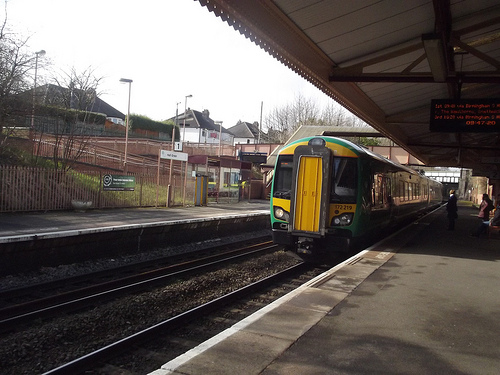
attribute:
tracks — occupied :
[42, 258, 327, 371]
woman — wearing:
[260, 128, 409, 253]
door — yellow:
[293, 155, 320, 230]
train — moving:
[265, 139, 452, 256]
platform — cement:
[147, 199, 498, 374]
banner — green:
[101, 171, 137, 191]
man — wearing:
[437, 185, 470, 237]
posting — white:
[159, 149, 187, 161]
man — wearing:
[442, 186, 462, 227]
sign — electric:
[425, 93, 499, 133]